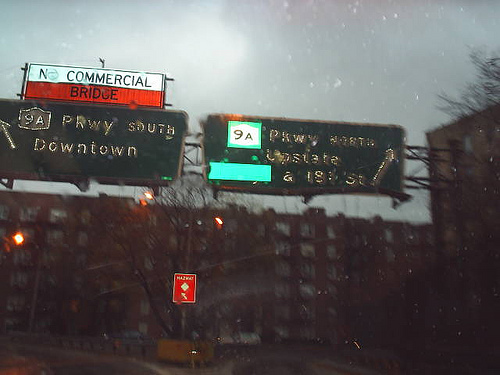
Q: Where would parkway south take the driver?
A: Downtown.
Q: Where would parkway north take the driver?
A: Upstate.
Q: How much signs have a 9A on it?
A: Two.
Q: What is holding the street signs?
A: A metal post.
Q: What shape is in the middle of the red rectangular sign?
A: A diamond.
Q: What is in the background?
A: A housing unit.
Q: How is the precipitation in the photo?
A: Rainy.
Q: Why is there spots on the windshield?
A: Rain drops.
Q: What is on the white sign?
A: No Commercial.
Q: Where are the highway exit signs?
A: Above the bridge.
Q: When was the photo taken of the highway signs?
A: Late rainy evening.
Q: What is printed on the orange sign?
A: Bridge.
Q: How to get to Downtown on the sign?
A: 9A Pkwy South.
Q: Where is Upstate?
A: 9A Pkwy North.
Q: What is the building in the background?
A: An apartment.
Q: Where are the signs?
A: On the bars.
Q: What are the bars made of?
A: Metal.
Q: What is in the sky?
A: Clouds.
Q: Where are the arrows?
A: On the signs.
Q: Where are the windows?
A: On the buildings.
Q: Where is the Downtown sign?
A: On the left.